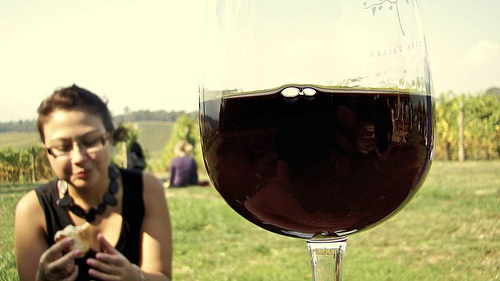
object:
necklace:
[56, 162, 122, 223]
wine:
[191, 80, 440, 240]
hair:
[167, 140, 196, 159]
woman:
[162, 137, 210, 189]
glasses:
[40, 128, 114, 159]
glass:
[181, 0, 443, 281]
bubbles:
[281, 86, 301, 98]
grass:
[413, 208, 486, 281]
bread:
[52, 221, 102, 259]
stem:
[306, 236, 346, 281]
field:
[0, 153, 500, 281]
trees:
[434, 88, 499, 165]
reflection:
[220, 92, 415, 232]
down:
[0, 202, 500, 281]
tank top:
[31, 165, 146, 281]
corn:
[0, 143, 59, 185]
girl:
[12, 83, 177, 281]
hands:
[33, 235, 89, 281]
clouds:
[9, 30, 165, 84]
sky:
[0, 0, 500, 124]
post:
[454, 107, 469, 163]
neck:
[55, 163, 114, 206]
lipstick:
[67, 167, 97, 179]